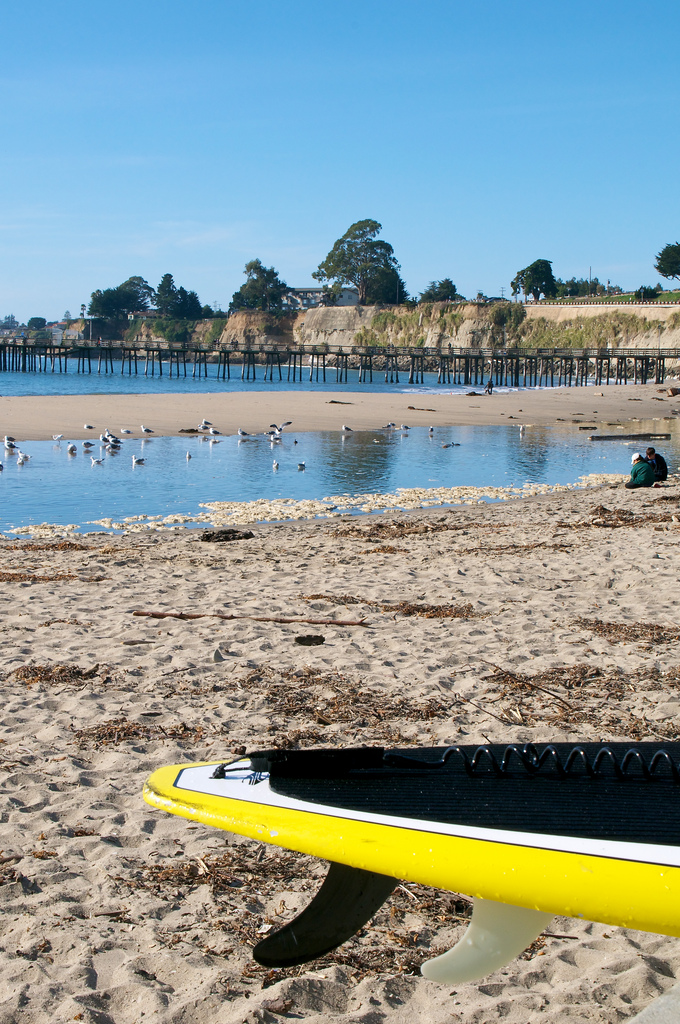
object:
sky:
[389, 98, 680, 229]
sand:
[488, 586, 575, 655]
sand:
[0, 775, 132, 1014]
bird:
[131, 454, 147, 467]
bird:
[186, 451, 192, 460]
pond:
[1, 421, 680, 541]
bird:
[297, 462, 306, 475]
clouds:
[0, 205, 309, 260]